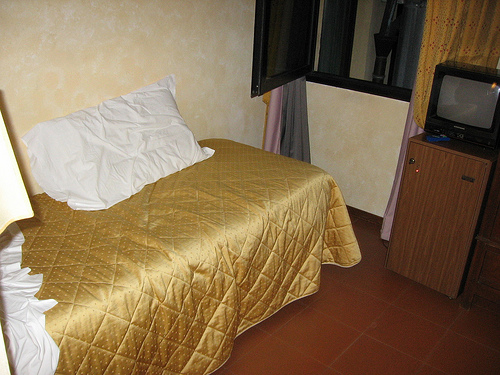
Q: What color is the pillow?
A: White.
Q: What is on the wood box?
A: Television.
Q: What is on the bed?
A: Pillow.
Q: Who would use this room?
A: Traveler.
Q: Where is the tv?
A: On the wood box.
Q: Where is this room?
A: Motel.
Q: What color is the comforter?
A: Gold.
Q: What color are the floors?
A: Brown.